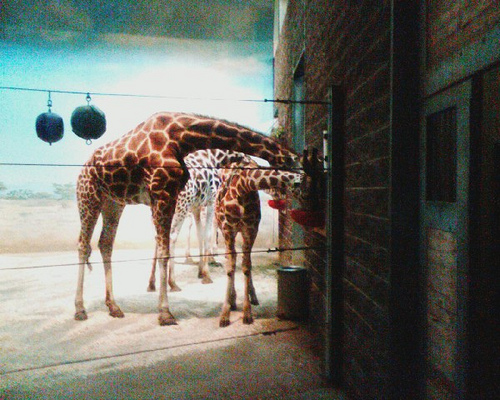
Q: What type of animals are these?
A: Giraffes.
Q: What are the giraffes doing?
A: Eating.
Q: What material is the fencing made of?
A: Wire.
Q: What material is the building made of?
A: Brick.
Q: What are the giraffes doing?
A: Eating.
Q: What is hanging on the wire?
A: Decorations.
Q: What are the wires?
A: Fencing.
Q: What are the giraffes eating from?
A: Red bowls.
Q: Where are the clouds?
A: In the sky.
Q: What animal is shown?
A: Giraffe.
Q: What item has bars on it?
A: A window.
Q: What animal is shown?
A: Giraffe.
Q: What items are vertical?
A: Wires.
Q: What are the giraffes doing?
A: Eating.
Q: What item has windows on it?
A: A building.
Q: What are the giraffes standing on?
A: Dirt.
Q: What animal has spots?
A: A giraffe.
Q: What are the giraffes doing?
A: Eating.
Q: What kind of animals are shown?
A: Giraffes.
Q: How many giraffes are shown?
A: Three.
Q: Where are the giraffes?
A: Beside the building.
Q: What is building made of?
A: Brick.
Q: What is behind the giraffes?
A: Trees.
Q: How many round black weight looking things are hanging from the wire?
A: Two.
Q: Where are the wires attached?
A: Side of building.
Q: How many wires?
A: Four.